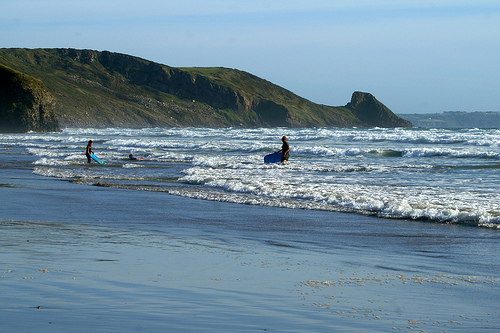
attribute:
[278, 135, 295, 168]
person — holding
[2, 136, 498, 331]
beach — isolated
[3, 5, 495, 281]
inlet — rocky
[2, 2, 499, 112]
blue sky — hazy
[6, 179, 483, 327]
shoreline — wet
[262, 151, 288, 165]
board — blue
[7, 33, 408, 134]
cliff — large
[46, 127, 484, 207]
waves — white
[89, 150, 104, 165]
boogie board — blue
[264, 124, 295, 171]
man — surfing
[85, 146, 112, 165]
boogey board — light blue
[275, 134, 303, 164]
woman — holding